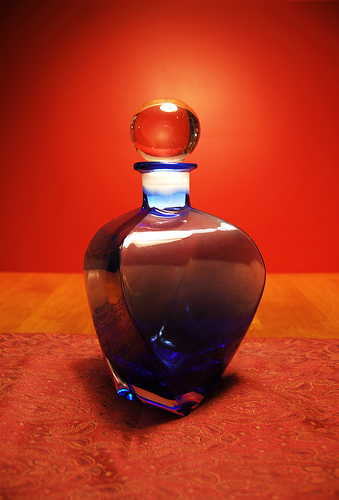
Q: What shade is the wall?
A: Red.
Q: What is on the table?
A: Jar.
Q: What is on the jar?
A: Cork.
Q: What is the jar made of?
A: Glass.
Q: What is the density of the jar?
A: Thick.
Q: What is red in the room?
A: Wall.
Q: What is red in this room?
A: The wall.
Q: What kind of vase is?
A: Blue glass.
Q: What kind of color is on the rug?
A: Red and gold paisley.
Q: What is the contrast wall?
A: Red.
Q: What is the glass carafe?
A: With topper.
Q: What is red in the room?
A: Wall.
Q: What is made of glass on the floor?
A: Vase.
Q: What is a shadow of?
A: Vase.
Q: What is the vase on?
A: Table.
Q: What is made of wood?
A: Table.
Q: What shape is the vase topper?
A: Circle.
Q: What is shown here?
A: Vase.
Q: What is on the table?
A: Red tablecloth.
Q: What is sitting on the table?
A: A vase.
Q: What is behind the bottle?
A: Red wall.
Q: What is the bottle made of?
A: Thick glass.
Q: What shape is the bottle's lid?
A: Round.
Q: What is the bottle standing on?
A: Red fabric.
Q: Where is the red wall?
A: Behind the bottle.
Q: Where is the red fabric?
A: Under the bottle.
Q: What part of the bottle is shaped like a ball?
A: The cork.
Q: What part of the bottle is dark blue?
A: The lower half.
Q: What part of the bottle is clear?
A: The cork.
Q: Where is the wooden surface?
A: Behind the bottle.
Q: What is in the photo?
A: A bottle.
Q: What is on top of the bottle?
A: A top.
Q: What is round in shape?
A: Top of the bottle.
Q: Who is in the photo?
A: No people.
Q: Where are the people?
A: None in photo.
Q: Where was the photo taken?
A: Inside somewhere.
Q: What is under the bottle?
A: Red surface.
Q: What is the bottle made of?
A: Glass.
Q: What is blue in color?
A: The bottle.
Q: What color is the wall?
A: Orange.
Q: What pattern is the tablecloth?
A: Paisley.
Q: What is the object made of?
A: Glass.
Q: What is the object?
A: Bottle.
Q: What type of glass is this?
A: Colored glass.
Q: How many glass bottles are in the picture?
A: 1.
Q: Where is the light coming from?
A: Above.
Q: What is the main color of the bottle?
A: Blue.